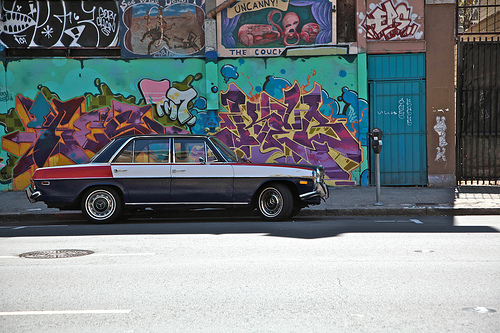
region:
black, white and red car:
[10, 124, 341, 231]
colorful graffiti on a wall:
[0, 80, 370, 191]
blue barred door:
[362, 49, 444, 194]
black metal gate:
[445, 27, 499, 201]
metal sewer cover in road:
[19, 246, 99, 271]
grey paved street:
[0, 210, 499, 331]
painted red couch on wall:
[233, 17, 281, 48]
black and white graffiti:
[2, 0, 124, 52]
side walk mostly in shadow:
[1, 185, 498, 215]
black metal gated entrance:
[447, 0, 499, 197]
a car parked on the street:
[16, 117, 331, 236]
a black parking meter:
[346, 108, 397, 212]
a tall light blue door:
[348, 33, 425, 188]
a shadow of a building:
[1, 192, 471, 250]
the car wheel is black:
[233, 177, 290, 229]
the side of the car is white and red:
[34, 160, 315, 192]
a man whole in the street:
[13, 219, 109, 278]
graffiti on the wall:
[200, 52, 355, 162]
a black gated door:
[443, 39, 498, 195]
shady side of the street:
[7, 86, 462, 256]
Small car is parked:
[21, 130, 331, 220]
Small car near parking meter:
[22, 130, 332, 222]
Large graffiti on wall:
[215, 70, 370, 186]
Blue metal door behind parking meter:
[366, 53, 430, 186]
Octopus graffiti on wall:
[267, 7, 314, 45]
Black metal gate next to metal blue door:
[455, 0, 498, 189]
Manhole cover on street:
[15, 246, 94, 258]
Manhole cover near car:
[15, 240, 99, 261]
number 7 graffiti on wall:
[165, 85, 197, 125]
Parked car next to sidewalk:
[25, 134, 328, 219]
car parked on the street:
[18, 120, 363, 229]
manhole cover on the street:
[11, 242, 102, 269]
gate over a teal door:
[366, 49, 437, 186]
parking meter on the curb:
[365, 123, 391, 213]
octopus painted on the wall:
[216, 3, 340, 51]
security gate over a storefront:
[457, 14, 492, 187]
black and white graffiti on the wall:
[6, 5, 118, 42]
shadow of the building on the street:
[143, 220, 462, 243]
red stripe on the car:
[32, 166, 117, 184]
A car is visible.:
[24, 108, 344, 246]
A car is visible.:
[78, 166, 356, 237]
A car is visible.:
[66, 128, 416, 288]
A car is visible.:
[61, 63, 276, 218]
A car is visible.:
[59, 147, 238, 244]